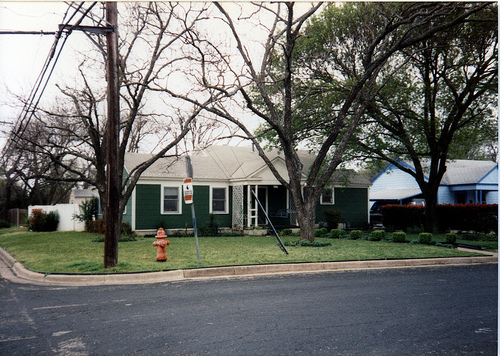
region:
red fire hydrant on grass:
[140, 225, 180, 266]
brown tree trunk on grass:
[87, 9, 128, 271]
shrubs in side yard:
[24, 205, 71, 229]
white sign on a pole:
[184, 179, 196, 196]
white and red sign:
[174, 173, 196, 203]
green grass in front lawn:
[167, 238, 245, 272]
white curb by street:
[154, 261, 298, 283]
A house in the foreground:
[88, 138, 380, 245]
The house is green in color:
[91, 135, 376, 240]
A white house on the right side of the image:
[363, 143, 497, 231]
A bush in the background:
[17, 205, 62, 238]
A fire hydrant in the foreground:
[148, 222, 181, 265]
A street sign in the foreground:
[173, 171, 218, 258]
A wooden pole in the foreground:
[60, 4, 148, 269]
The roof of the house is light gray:
[121, 133, 370, 189]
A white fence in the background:
[23, 197, 90, 236]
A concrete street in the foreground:
[0, 252, 495, 354]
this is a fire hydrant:
[136, 218, 191, 287]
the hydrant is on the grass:
[139, 211, 181, 268]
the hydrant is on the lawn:
[145, 200, 181, 284]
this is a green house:
[79, 120, 382, 247]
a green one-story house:
[93, 118, 382, 243]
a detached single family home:
[92, 110, 384, 240]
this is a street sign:
[164, 154, 219, 249]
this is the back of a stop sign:
[175, 145, 202, 182]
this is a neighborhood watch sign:
[174, 164, 200, 210]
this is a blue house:
[367, 130, 497, 215]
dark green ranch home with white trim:
[123, 152, 369, 233]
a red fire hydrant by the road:
[151, 225, 169, 260]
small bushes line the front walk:
[278, 224, 459, 249]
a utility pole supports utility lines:
[56, 1, 121, 268]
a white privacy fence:
[23, 205, 88, 229]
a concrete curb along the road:
[0, 252, 491, 286]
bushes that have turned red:
[386, 204, 498, 234]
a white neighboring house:
[373, 165, 498, 224]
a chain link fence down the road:
[0, 205, 32, 226]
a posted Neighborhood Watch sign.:
[180, 176, 193, 204]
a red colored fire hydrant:
[152, 224, 169, 262]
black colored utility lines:
[2, 0, 104, 168]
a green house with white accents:
[113, 151, 369, 235]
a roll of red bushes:
[376, 203, 494, 237]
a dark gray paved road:
[1, 251, 496, 353]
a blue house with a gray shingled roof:
[366, 153, 498, 206]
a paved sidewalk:
[452, 242, 496, 257]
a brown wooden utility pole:
[101, 0, 119, 266]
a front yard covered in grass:
[0, 227, 490, 282]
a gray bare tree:
[130, 0, 489, 245]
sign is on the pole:
[180, 174, 191, 200]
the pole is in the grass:
[180, 156, 215, 264]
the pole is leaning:
[240, 185, 287, 257]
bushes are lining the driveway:
[348, 221, 462, 255]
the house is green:
[124, 183, 362, 240]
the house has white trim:
[134, 175, 366, 233]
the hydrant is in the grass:
[146, 226, 177, 266]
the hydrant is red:
[153, 235, 171, 260]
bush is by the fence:
[24, 211, 70, 236]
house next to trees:
[72, 113, 398, 264]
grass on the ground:
[208, 229, 273, 267]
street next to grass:
[205, 279, 357, 325]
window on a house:
[303, 157, 353, 228]